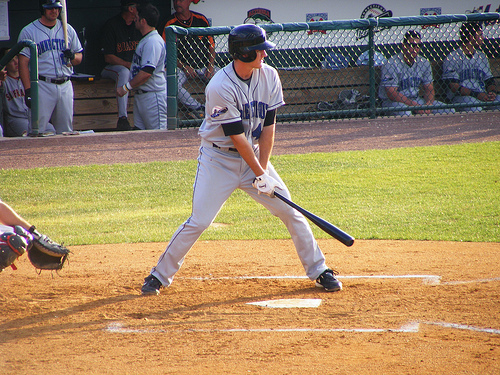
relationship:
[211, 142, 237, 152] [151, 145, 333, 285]
belt on pants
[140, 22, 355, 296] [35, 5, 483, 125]
baseball player sitting in dugout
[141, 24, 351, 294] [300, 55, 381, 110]
baseball player sitting on bench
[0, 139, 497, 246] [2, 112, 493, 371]
grass on field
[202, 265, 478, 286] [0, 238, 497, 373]
line in dirt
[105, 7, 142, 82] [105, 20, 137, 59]
man wearing black shirt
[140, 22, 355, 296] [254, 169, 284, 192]
baseball player wearing glove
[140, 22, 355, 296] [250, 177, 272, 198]
baseball player wearing glove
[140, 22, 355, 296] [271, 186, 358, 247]
baseball player holding bat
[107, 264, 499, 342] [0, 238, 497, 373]
lines in dirt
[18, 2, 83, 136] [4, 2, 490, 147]
player in dugout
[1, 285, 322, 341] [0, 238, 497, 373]
shadows on dirt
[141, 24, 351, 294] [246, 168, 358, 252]
baseball player holding bat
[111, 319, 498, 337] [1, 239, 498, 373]
lines on sand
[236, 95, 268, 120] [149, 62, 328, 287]
blue letters on gray uniform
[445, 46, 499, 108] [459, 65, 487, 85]
gray uniform on blue letters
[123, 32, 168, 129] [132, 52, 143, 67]
gray uniform on blue letters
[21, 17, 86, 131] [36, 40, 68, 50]
gray uniform on blue letters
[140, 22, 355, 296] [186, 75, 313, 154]
baseball player wearing shirt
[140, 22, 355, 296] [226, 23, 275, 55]
baseball player wearing helmet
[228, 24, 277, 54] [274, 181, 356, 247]
baseball cap on bat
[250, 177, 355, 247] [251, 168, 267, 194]
bat in hand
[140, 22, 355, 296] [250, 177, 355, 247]
baseball player holding bat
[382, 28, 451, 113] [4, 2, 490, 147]
baseball player sitting in dugout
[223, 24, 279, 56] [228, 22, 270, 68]
baseball cap on head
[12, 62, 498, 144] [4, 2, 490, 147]
bench in dugout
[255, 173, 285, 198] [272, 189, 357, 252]
hand on bat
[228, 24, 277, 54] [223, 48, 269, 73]
baseball cap on head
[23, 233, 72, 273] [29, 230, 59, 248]
glove on hand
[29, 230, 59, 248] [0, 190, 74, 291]
hand of catcher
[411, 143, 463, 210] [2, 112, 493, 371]
grass on field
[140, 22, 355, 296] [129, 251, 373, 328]
baseball player wearing sneakers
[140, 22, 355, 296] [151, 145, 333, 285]
baseball player wearing pants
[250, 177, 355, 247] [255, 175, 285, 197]
bat in a hand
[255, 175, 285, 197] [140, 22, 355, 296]
hand of baseball player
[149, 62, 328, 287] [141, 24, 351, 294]
gray uniform on baseball player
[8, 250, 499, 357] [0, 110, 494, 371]
dirt on ground